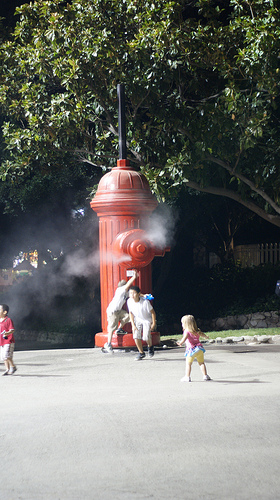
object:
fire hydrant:
[90, 79, 172, 347]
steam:
[0, 199, 174, 331]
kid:
[174, 312, 213, 382]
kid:
[0, 302, 17, 374]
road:
[0, 342, 280, 498]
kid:
[104, 274, 136, 352]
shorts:
[186, 349, 207, 364]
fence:
[201, 242, 279, 270]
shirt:
[0, 315, 14, 345]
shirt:
[183, 328, 202, 348]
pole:
[115, 80, 126, 167]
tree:
[0, 0, 280, 229]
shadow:
[210, 375, 269, 388]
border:
[205, 307, 280, 329]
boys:
[126, 285, 158, 360]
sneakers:
[133, 349, 145, 360]